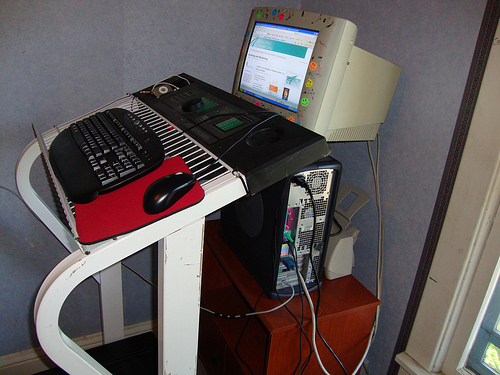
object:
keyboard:
[48, 107, 164, 205]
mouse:
[141, 171, 197, 215]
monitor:
[231, 7, 403, 141]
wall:
[1, 4, 480, 374]